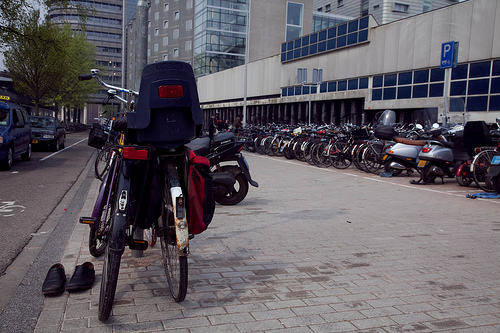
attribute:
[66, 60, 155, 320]
bike — purple, black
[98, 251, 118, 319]
tire — rubber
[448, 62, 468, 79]
window — rectangular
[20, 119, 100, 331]
road — is paved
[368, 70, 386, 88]
window — rectangular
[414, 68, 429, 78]
window — rectangular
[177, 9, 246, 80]
building — mirrored glass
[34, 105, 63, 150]
car — is dark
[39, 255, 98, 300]
shoes — black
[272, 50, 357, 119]
lights — gray, metal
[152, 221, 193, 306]
tire — black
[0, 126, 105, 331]
street — asphalt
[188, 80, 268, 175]
man — dressed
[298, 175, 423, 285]
ground — concrete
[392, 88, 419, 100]
window — rectangular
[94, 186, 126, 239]
fender — metal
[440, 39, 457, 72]
parking sign — blue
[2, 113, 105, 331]
road — is dark, is gray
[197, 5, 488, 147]
building — is grey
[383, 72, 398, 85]
window — rectangular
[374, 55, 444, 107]
window — rectangular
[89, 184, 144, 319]
tire — black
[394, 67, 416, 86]
window — rectangular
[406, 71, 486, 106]
window — rectangular